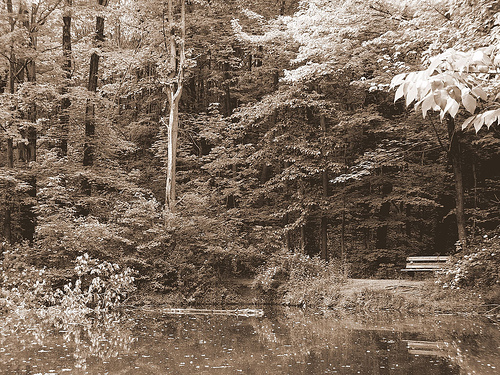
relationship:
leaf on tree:
[333, 176, 345, 184] [308, 100, 498, 260]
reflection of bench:
[397, 332, 469, 362] [398, 255, 452, 281]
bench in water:
[398, 255, 452, 281] [5, 297, 497, 374]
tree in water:
[0, 272, 264, 344] [5, 297, 497, 374]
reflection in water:
[398, 337, 456, 360] [5, 297, 497, 374]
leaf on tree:
[115, 216, 122, 222] [65, 200, 193, 291]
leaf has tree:
[196, 196, 263, 261] [179, 104, 295, 294]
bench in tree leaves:
[398, 253, 451, 285] [385, 70, 407, 95]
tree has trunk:
[92, 0, 247, 203] [162, 107, 177, 202]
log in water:
[159, 304, 265, 317] [5, 297, 497, 374]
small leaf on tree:
[422, 96, 435, 116] [374, 26, 498, 262]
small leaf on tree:
[326, 160, 348, 175] [185, 76, 415, 246]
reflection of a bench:
[398, 337, 456, 360] [400, 253, 457, 283]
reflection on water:
[398, 337, 456, 360] [0, 291, 497, 372]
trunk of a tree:
[78, 0, 110, 215] [61, 0, 151, 218]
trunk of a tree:
[167, 76, 179, 207] [95, 38, 487, 336]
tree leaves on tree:
[0, 20, 498, 348] [119, 9, 239, 248]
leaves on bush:
[100, 223, 155, 271] [115, 189, 245, 299]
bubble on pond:
[196, 337, 209, 345] [2, 299, 494, 371]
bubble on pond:
[386, 338, 396, 344] [2, 299, 494, 371]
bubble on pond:
[139, 353, 151, 360] [2, 299, 494, 371]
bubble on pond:
[378, 363, 387, 370] [2, 299, 494, 371]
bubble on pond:
[139, 352, 151, 358] [2, 299, 494, 371]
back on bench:
[407, 252, 452, 265] [397, 252, 459, 280]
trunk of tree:
[160, 27, 180, 207] [129, 3, 222, 214]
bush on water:
[0, 252, 137, 374] [5, 297, 497, 374]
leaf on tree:
[202, 212, 209, 219] [4, 2, 45, 274]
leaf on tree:
[145, 231, 153, 240] [25, 1, 75, 290]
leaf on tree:
[162, 67, 170, 76] [79, 1, 171, 296]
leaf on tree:
[267, 215, 279, 227] [189, 2, 322, 304]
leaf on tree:
[273, 84, 276, 90] [240, 3, 456, 282]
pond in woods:
[2, 299, 494, 371] [1, 0, 498, 319]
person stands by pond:
[218, 285, 230, 306] [0, 298, 499, 374]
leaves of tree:
[391, 59, 479, 129] [36, 18, 136, 169]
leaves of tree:
[243, 11, 482, 157] [101, 60, 185, 147]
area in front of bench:
[303, 254, 442, 312] [401, 254, 453, 280]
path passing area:
[226, 268, 259, 288] [318, 251, 445, 315]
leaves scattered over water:
[12, 327, 205, 369] [6, 309, 488, 370]